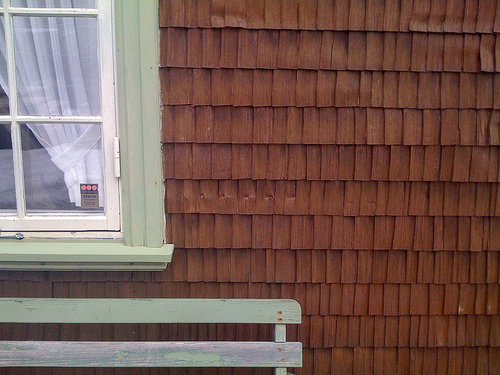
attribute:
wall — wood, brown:
[191, 152, 481, 275]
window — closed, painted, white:
[0, 1, 174, 276]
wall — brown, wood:
[0, 1, 497, 373]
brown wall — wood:
[13, 0, 491, 364]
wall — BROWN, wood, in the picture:
[157, 2, 499, 370]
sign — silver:
[67, 169, 105, 215]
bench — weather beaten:
[0, 292, 305, 372]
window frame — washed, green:
[1, 1, 179, 272]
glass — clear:
[18, 121, 110, 217]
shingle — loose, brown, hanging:
[478, 33, 495, 73]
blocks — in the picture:
[261, 235, 346, 292]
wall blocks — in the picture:
[463, 110, 497, 155]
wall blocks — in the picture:
[390, 216, 417, 253]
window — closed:
[8, 13, 121, 232]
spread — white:
[2, 148, 70, 204]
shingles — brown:
[180, 139, 497, 244]